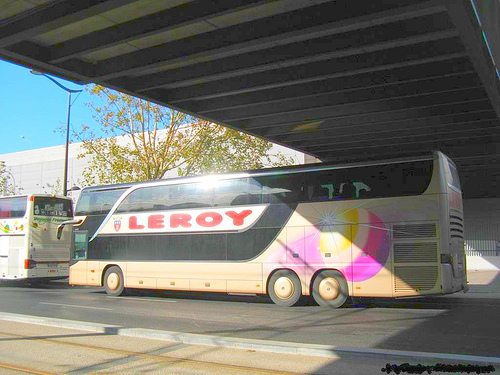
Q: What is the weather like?
A: It is clear.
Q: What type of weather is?
A: It is clear.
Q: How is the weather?
A: It is clear.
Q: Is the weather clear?
A: Yes, it is clear.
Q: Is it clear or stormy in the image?
A: It is clear.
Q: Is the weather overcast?
A: No, it is clear.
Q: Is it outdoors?
A: Yes, it is outdoors.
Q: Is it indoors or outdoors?
A: It is outdoors.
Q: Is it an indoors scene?
A: No, it is outdoors.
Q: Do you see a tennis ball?
A: No, there are no tennis balls.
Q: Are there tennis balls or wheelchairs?
A: No, there are no tennis balls or wheelchairs.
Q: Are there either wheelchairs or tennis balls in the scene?
A: No, there are no tennis balls or wheelchairs.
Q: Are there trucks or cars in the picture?
A: No, there are no cars or trucks.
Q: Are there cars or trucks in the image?
A: No, there are no cars or trucks.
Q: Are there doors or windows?
A: Yes, there is a window.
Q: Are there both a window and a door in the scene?
A: Yes, there are both a window and a door.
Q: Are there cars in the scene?
A: No, there are no cars.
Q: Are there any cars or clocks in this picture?
A: No, there are no cars or clocks.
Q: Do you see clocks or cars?
A: No, there are no cars or clocks.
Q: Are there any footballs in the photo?
A: No, there are no footballs.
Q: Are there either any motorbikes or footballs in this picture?
A: No, there are no footballs or motorbikes.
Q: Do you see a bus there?
A: Yes, there is a bus.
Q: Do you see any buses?
A: Yes, there is a bus.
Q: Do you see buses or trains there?
A: Yes, there is a bus.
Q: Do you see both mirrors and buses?
A: Yes, there are both a bus and a mirror.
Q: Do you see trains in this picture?
A: No, there are no trains.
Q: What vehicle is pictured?
A: The vehicle is a bus.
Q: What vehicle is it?
A: The vehicle is a bus.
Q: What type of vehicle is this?
A: This is a bus.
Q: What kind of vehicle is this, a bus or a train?
A: This is a bus.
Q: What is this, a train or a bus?
A: This is a bus.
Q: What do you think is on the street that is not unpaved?
A: The bus is on the street.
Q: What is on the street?
A: The bus is on the street.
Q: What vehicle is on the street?
A: The vehicle is a bus.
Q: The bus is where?
A: The bus is on the street.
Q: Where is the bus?
A: The bus is on the street.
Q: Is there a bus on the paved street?
A: Yes, there is a bus on the street.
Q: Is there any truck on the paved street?
A: No, there is a bus on the street.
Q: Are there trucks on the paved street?
A: No, there is a bus on the street.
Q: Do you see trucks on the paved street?
A: No, there is a bus on the street.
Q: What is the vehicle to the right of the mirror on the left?
A: The vehicle is a bus.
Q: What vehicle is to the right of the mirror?
A: The vehicle is a bus.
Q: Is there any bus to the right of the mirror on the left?
A: Yes, there is a bus to the right of the mirror.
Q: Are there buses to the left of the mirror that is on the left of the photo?
A: No, the bus is to the right of the mirror.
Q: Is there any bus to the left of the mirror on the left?
A: No, the bus is to the right of the mirror.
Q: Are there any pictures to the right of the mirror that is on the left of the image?
A: No, there is a bus to the right of the mirror.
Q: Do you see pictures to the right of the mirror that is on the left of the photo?
A: No, there is a bus to the right of the mirror.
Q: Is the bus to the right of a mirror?
A: Yes, the bus is to the right of a mirror.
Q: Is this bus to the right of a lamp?
A: No, the bus is to the right of a mirror.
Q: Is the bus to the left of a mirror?
A: No, the bus is to the right of a mirror.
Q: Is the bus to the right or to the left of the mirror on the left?
A: The bus is to the right of the mirror.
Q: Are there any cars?
A: No, there are no cars.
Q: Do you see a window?
A: Yes, there is a window.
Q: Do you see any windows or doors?
A: Yes, there is a window.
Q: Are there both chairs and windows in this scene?
A: No, there is a window but no chairs.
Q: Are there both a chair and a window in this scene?
A: No, there is a window but no chairs.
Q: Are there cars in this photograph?
A: No, there are no cars.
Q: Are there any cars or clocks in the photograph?
A: No, there are no cars or clocks.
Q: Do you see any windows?
A: Yes, there is a window.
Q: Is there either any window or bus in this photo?
A: Yes, there is a window.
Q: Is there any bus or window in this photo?
A: Yes, there is a window.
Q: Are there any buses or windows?
A: Yes, there is a window.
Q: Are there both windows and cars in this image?
A: No, there is a window but no cars.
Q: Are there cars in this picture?
A: No, there are no cars.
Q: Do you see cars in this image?
A: No, there are no cars.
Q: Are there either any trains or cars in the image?
A: No, there are no cars or trains.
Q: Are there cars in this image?
A: No, there are no cars.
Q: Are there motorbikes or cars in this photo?
A: No, there are no cars or motorbikes.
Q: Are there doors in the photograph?
A: Yes, there is a door.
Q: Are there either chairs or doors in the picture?
A: Yes, there is a door.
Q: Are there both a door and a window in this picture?
A: Yes, there are both a door and a window.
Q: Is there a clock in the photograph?
A: No, there are no clocks.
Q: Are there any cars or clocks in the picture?
A: No, there are no clocks or cars.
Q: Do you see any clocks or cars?
A: No, there are no clocks or cars.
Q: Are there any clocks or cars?
A: No, there are no clocks or cars.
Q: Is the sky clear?
A: Yes, the sky is clear.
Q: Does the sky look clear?
A: Yes, the sky is clear.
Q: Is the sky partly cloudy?
A: No, the sky is clear.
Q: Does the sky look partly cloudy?
A: No, the sky is clear.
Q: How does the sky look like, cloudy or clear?
A: The sky is clear.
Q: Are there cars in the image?
A: No, there are no cars.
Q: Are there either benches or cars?
A: No, there are no cars or benches.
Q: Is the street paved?
A: Yes, the street is paved.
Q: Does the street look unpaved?
A: No, the street is paved.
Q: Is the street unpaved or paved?
A: The street is paved.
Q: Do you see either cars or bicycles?
A: No, there are no cars or bicycles.